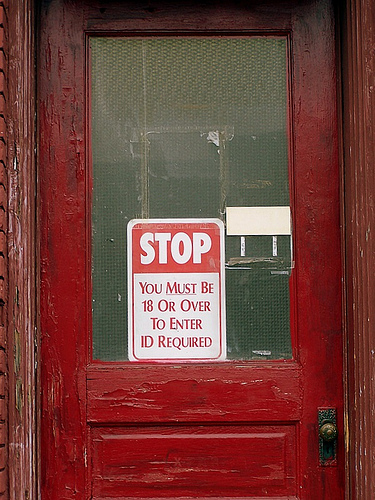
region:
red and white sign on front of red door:
[120, 211, 231, 367]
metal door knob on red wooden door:
[317, 406, 339, 467]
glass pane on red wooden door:
[84, 36, 297, 365]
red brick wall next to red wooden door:
[0, 5, 11, 205]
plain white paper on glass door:
[221, 205, 293, 241]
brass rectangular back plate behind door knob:
[313, 405, 341, 466]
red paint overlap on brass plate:
[321, 456, 342, 468]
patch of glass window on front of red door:
[235, 299, 283, 348]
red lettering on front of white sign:
[135, 279, 213, 352]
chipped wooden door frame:
[344, 141, 372, 279]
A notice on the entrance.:
[127, 216, 225, 361]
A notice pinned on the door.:
[119, 216, 233, 362]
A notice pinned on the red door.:
[38, 6, 345, 498]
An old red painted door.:
[39, 3, 343, 495]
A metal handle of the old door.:
[318, 402, 337, 468]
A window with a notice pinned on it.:
[82, 35, 292, 362]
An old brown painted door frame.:
[0, 1, 40, 491]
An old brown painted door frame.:
[340, 0, 370, 495]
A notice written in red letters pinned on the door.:
[121, 217, 227, 360]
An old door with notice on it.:
[35, 1, 356, 498]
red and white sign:
[126, 215, 227, 360]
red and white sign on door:
[126, 216, 229, 361]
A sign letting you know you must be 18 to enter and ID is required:
[123, 215, 224, 361]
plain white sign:
[223, 203, 291, 236]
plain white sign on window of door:
[223, 197, 292, 237]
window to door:
[89, 36, 291, 359]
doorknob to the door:
[316, 405, 340, 467]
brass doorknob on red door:
[314, 406, 339, 469]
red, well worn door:
[41, 2, 345, 497]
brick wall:
[0, 1, 7, 498]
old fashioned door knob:
[312, 399, 338, 480]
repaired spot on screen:
[129, 121, 234, 219]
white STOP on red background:
[136, 225, 214, 275]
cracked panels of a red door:
[85, 366, 293, 496]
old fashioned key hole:
[318, 444, 337, 467]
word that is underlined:
[162, 278, 199, 298]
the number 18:
[138, 296, 155, 315]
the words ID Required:
[138, 333, 216, 353]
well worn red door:
[43, 8, 335, 498]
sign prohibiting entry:
[128, 217, 230, 369]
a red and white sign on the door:
[124, 211, 230, 363]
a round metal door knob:
[317, 421, 343, 442]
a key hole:
[323, 442, 332, 459]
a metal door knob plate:
[314, 402, 338, 472]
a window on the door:
[86, 32, 294, 360]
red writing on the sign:
[132, 272, 216, 357]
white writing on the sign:
[136, 229, 213, 267]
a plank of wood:
[82, 357, 304, 422]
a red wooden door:
[38, 0, 349, 496]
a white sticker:
[222, 204, 291, 239]